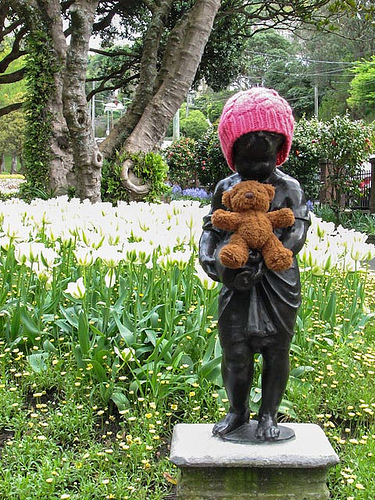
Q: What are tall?
A: Trees.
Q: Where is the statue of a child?
A: In garden.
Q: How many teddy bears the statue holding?
A: One.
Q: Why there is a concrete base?
A: To hold the statue.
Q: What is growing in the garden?
A: Flowers.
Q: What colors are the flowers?
A: White.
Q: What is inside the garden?
A: Huge tree.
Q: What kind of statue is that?
A: A child.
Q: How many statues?
A: One.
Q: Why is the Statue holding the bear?
A: Remembrance.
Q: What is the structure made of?
A: Granite.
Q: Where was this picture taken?
A: Garden plot.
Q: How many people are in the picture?
A: One lineman.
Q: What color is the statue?
A: Black.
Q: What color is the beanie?
A: Pink.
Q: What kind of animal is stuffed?
A: Bear.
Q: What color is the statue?
A: Black.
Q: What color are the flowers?
A: White.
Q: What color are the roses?
A: Red.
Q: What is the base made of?
A: Concrete.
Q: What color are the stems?
A: Green.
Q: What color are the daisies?
A: Yellow.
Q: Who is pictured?
A: A statue.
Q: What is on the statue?
A: A pink hat.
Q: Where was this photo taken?
A: At a park.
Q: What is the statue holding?
A: A brown teddy bear.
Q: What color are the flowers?
A: They are white.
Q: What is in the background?
A: Trees and flowers.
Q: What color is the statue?
A: It is black.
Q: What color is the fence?
A: It is black.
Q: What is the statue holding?
A: A teddy bear.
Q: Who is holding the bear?
A: The statue.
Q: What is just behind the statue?
A: Flowers.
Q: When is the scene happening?
A: Daytime.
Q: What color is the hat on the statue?
A: Pink.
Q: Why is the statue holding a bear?
A: Someone put it there.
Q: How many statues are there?
A: 1.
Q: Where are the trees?
A: Background.